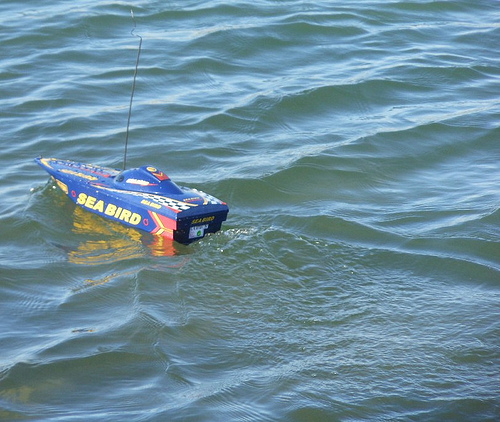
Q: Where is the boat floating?
A: In the water.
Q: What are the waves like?
A: Wavy small swells.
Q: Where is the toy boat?
A: In the water.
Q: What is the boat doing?
A: Floating in the water.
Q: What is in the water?
A: A toy boat.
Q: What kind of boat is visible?
A: A toy.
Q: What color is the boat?
A: Blue, yellow, and orange.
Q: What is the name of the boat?
A: Seabird.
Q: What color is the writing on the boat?
A: Yellow.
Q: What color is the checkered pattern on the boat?
A: White and black.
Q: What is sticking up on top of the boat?
A: Antenna.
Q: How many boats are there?
A: 1.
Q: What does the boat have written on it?
A: Sea bird.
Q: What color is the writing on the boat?
A: Yellow.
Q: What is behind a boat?
A: A wake in the water.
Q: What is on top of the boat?
A: An antenna.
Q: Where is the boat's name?
A: On the side of the boat.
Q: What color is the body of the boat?
A: Blue.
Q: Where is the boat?
A: In the water.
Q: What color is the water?
A: Blue.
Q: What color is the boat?
A: Blue.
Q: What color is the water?
A: Blue.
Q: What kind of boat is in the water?
A: Toy.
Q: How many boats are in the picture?
A: One.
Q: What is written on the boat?
A: Sea Bird.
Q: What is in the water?
A: A boat.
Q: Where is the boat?
A: In the water.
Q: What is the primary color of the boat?
A: Blue.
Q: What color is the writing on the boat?
A: Yellow.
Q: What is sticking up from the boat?
A: An antenna.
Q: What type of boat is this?
A: Radio controlled.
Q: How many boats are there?
A: One.